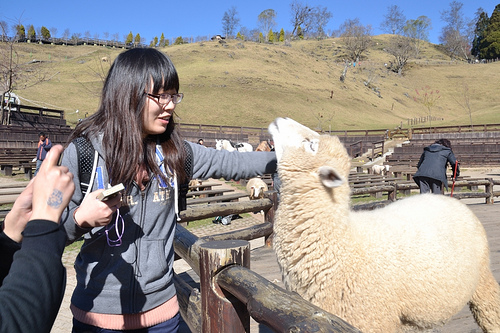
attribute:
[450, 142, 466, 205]
handle — red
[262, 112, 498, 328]
sheep — beige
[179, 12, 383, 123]
hill — brown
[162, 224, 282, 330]
fence — wood